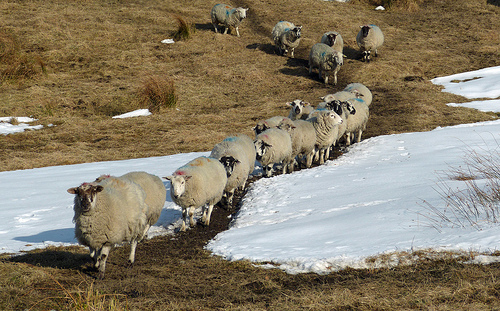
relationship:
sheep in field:
[186, 161, 225, 187] [105, 45, 212, 82]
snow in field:
[472, 75, 487, 91] [105, 45, 212, 82]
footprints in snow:
[368, 129, 408, 155] [472, 75, 487, 91]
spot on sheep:
[188, 159, 203, 167] [186, 161, 225, 187]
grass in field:
[7, 41, 86, 98] [105, 45, 212, 82]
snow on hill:
[472, 75, 487, 91] [373, 177, 453, 256]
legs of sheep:
[303, 68, 342, 85] [186, 161, 225, 187]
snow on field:
[472, 75, 487, 91] [105, 45, 212, 82]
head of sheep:
[293, 79, 345, 133] [186, 161, 225, 187]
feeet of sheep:
[212, 23, 274, 57] [186, 161, 225, 187]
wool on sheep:
[321, 44, 325, 59] [186, 161, 225, 187]